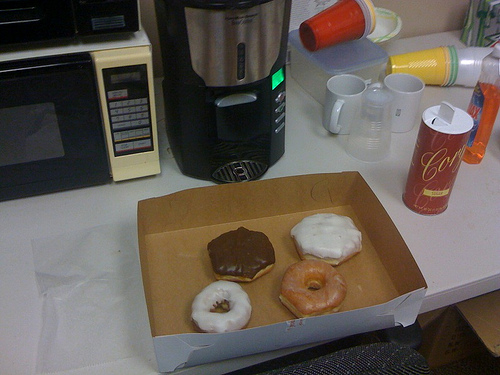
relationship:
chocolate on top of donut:
[210, 234, 270, 270] [205, 225, 279, 284]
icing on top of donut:
[297, 220, 350, 248] [291, 213, 373, 261]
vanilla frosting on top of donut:
[191, 284, 248, 328] [187, 277, 257, 336]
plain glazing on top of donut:
[291, 267, 333, 306] [281, 258, 349, 318]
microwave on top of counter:
[3, 45, 162, 203] [2, 31, 497, 371]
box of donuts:
[139, 171, 427, 368] [195, 211, 363, 333]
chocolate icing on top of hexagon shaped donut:
[210, 234, 270, 270] [205, 225, 279, 284]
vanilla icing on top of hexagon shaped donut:
[297, 220, 350, 248] [291, 213, 373, 261]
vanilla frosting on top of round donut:
[191, 280, 249, 331] [191, 284, 248, 328]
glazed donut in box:
[281, 258, 349, 318] [139, 171, 427, 368]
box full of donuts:
[135, 171, 430, 374] [195, 211, 363, 333]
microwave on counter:
[3, 45, 162, 203] [2, 31, 497, 371]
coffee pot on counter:
[159, 3, 300, 173] [2, 31, 497, 371]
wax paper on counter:
[37, 232, 146, 371] [2, 31, 497, 371]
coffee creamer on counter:
[409, 107, 465, 219] [2, 31, 497, 371]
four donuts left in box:
[195, 211, 363, 333] [139, 171, 427, 368]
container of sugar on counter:
[409, 107, 465, 219] [2, 31, 497, 371]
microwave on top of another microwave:
[1, 3, 152, 39] [3, 45, 162, 203]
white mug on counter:
[323, 78, 367, 132] [2, 31, 497, 371]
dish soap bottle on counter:
[466, 44, 499, 165] [2, 31, 497, 371]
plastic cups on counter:
[352, 92, 393, 156] [2, 31, 497, 371]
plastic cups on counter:
[303, 10, 372, 42] [2, 31, 497, 371]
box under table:
[135, 171, 430, 374] [2, 31, 497, 371]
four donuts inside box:
[195, 211, 363, 333] [139, 171, 427, 368]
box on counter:
[135, 171, 430, 374] [2, 31, 497, 371]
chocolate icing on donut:
[210, 234, 270, 270] [205, 225, 279, 284]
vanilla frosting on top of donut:
[191, 284, 248, 328] [291, 213, 373, 261]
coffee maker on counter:
[159, 3, 300, 173] [2, 31, 497, 371]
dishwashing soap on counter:
[466, 44, 499, 165] [2, 31, 497, 371]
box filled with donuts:
[135, 171, 430, 374] [195, 211, 363, 333]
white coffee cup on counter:
[378, 77, 421, 136] [2, 31, 497, 371]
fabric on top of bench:
[299, 352, 429, 368] [266, 340, 436, 375]